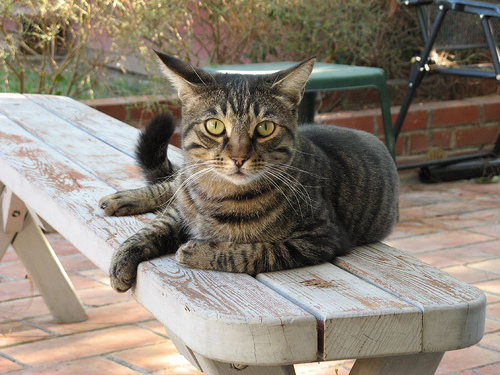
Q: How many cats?
A: 1.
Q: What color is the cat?
A: Brown.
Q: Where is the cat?
A: On the bench.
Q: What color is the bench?
A: Blue.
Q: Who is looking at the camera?
A: The cat.